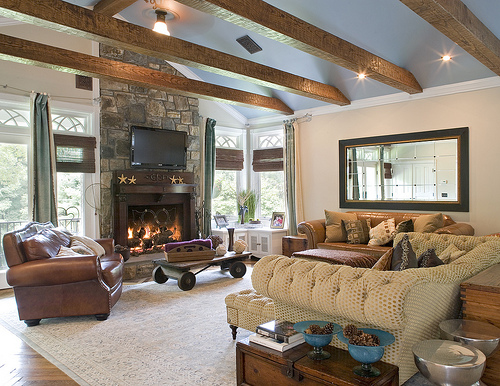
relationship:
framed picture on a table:
[268, 209, 286, 231] [245, 221, 287, 256]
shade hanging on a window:
[248, 145, 288, 174] [223, 123, 298, 201]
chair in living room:
[2, 220, 126, 330] [0, 0, 496, 378]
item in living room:
[151, 241, 251, 292] [0, 0, 496, 378]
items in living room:
[288, 310, 395, 370] [0, 0, 496, 378]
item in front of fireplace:
[151, 241, 251, 292] [117, 176, 197, 251]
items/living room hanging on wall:
[335, 135, 470, 210] [288, 84, 497, 239]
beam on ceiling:
[1, 0, 500, 116] [335, 16, 432, 61]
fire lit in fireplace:
[129, 221, 177, 246] [115, 169, 195, 245]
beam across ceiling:
[1, 32, 297, 114] [67, 1, 497, 121]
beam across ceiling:
[1, 0, 500, 116] [67, 1, 497, 121]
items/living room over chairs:
[335, 135, 470, 210] [298, 207, 476, 252]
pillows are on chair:
[388, 234, 463, 271] [218, 213, 500, 368]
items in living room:
[163, 234, 216, 262] [0, 0, 496, 378]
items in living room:
[173, 173, 185, 185] [0, 0, 496, 378]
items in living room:
[125, 175, 138, 185] [0, 0, 496, 378]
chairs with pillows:
[298, 207, 476, 252] [366, 211, 398, 246]